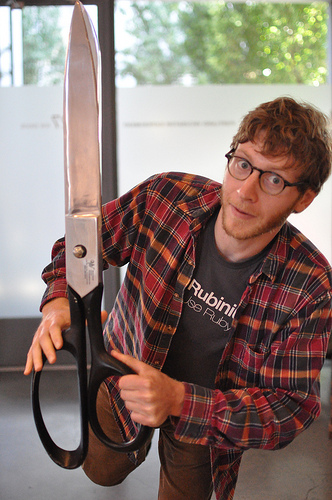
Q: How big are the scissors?
A: Huge.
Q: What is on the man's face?
A: Beard.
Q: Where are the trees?
A: Outside the window.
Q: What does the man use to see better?
A: Eyeglasses.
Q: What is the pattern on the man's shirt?
A: Plaid.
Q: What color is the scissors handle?
A: Black.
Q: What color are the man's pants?
A: Brown.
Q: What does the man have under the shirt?
A: A t-shirt.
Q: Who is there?
A: Nerdy man.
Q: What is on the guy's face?
A: Glasses.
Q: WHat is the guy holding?
A: Scissors.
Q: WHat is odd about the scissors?
A: Huge.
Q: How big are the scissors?
A: Very big.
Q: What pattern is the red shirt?
A: Plaid.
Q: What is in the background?
A: Window.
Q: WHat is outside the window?
A: Trees.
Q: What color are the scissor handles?
A: Black.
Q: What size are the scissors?
A: Big.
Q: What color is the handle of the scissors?
A: Black.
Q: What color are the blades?
A: Silver.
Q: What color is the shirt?
A: Black.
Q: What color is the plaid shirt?
A: Red.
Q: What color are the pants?
A: Brown.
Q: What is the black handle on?
A: Giant scissors.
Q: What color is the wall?
A: White.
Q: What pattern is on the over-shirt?
A: Plaid.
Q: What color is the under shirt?
A: Gray.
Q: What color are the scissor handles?
A: Black.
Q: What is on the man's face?
A: A pair of glasses.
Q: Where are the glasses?
A: On the man's face.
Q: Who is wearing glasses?
A: The man.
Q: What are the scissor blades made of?
A: Metal.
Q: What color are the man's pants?
A: Brown.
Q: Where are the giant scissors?
A: In the man's hands.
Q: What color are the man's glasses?
A: Black.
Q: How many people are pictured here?
A: One.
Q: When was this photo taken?
A: Daytime.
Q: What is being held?
A: Large scissors.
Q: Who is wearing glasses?
A: Man.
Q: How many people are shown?
A: 1.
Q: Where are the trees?
A: Outside of the window.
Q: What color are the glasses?
A: Black.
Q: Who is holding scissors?
A: A man.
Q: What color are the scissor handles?
A: Black.